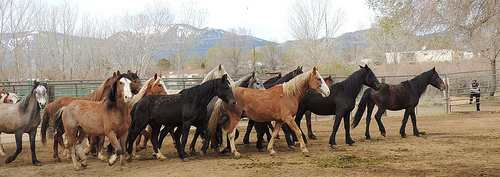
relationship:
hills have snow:
[59, 26, 240, 59] [168, 19, 204, 52]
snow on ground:
[163, 75, 193, 109] [144, 112, 491, 148]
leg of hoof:
[397, 101, 415, 139] [301, 151, 310, 157]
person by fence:
[465, 69, 499, 109] [445, 68, 470, 122]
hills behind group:
[0, 24, 499, 79] [0, 63, 445, 171]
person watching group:
[465, 69, 499, 109] [0, 63, 445, 171]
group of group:
[26, 81, 236, 139] [0, 63, 445, 171]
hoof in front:
[301, 151, 310, 157] [377, 61, 457, 142]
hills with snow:
[0, 24, 499, 79] [168, 19, 204, 52]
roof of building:
[436, 38, 474, 51] [388, 41, 486, 68]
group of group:
[0, 63, 445, 171] [0, 63, 445, 171]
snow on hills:
[168, 19, 204, 52] [0, 24, 499, 79]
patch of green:
[343, 148, 356, 166] [323, 156, 337, 169]